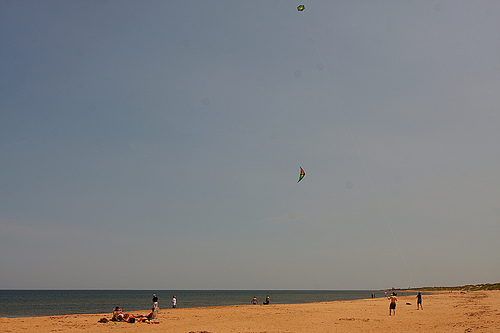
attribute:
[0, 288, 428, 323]
water — blue dark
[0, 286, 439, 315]
water — calm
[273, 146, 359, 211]
kite — flying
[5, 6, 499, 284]
sky — hazy, overcast, clear, blue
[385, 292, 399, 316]
person — shirtless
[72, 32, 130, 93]
clouds — white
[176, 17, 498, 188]
sky — blue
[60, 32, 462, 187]
sky — blue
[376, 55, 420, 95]
clouds — white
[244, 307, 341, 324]
sand — tan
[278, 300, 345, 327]
sand — level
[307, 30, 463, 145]
sky — white, blue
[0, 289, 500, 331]
beach — sandy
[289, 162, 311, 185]
kite — colorful